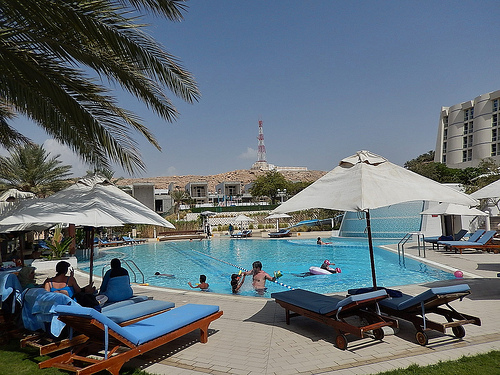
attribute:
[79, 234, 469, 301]
pool — blue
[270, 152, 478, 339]
umbrella — large, white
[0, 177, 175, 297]
umbrella — large, white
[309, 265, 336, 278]
float toy — white, purple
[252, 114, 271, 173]
pillar — white, metal, red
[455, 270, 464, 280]
ball — pink, plastic, purple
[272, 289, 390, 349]
lounge chair — blue, brown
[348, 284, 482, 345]
lounge chair — blue, brown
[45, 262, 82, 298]
woman — sitting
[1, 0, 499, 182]
sky — blue